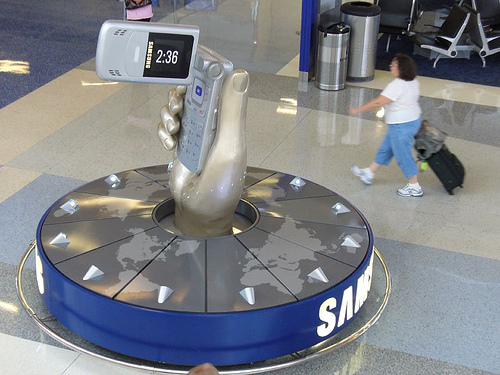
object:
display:
[19, 18, 393, 371]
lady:
[344, 52, 426, 202]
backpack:
[416, 117, 466, 198]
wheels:
[446, 184, 463, 196]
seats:
[413, 2, 499, 71]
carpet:
[3, 1, 99, 100]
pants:
[377, 115, 421, 181]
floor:
[7, 79, 170, 199]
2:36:
[155, 48, 181, 65]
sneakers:
[350, 165, 427, 200]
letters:
[144, 38, 155, 71]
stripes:
[399, 187, 424, 192]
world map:
[72, 169, 366, 307]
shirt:
[382, 78, 421, 125]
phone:
[93, 17, 235, 177]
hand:
[157, 69, 251, 238]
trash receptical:
[312, 0, 386, 94]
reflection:
[267, 86, 304, 122]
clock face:
[143, 32, 188, 79]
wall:
[302, 1, 349, 72]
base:
[35, 219, 377, 367]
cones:
[154, 281, 267, 312]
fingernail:
[229, 73, 251, 95]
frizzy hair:
[398, 53, 417, 81]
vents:
[108, 27, 134, 77]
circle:
[16, 237, 392, 374]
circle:
[148, 197, 262, 242]